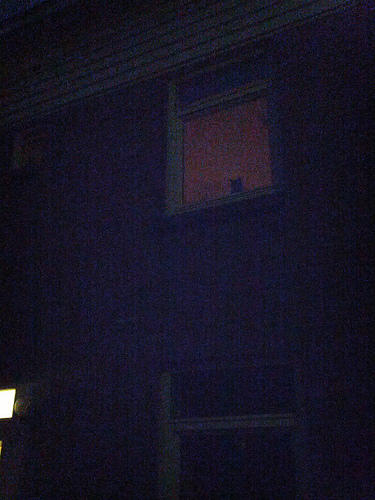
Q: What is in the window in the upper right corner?
A: Silhouette of an animal.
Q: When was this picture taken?
A: During the night.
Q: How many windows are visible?
A: 2.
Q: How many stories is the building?
A: 2.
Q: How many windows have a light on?
A: 1.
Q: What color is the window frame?
A: White.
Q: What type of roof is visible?
A: Shingled.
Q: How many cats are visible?
A: 1.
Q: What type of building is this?
A: House.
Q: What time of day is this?
A: Evening.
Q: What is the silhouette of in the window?
A: Animal.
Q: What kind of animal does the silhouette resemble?
A: Cat.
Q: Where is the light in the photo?
A: Window.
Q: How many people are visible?
A: None.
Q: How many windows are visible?
A: Two.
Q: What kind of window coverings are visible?
A: None.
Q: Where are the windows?
A: Side of building.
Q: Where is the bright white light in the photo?
A: Lower left hand side.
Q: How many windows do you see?
A: 2.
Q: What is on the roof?
A: Shingles.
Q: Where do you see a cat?
A: The window.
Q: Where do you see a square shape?
A: The windows.